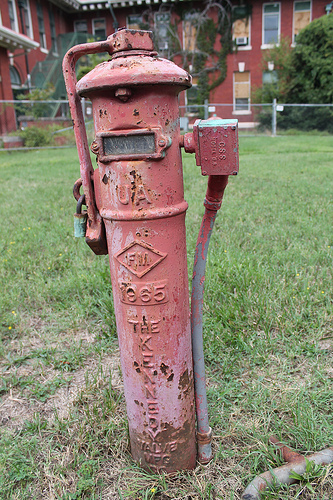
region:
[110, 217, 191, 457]
raised metal lettering of the fire hydrant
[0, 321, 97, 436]
sparse patches of brown dirt on the ground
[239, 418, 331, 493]
grey metal pipe on the ground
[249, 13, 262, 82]
red brick wall of the building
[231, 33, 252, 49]
an air conditioner in a window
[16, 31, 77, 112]
green cage over the stairwell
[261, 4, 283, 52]
white trim of the window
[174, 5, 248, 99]
green vines growing on the building wall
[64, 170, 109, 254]
rusted lock on the fire hydrant lever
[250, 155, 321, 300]
green grass of the courtyard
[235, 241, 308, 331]
green grass of the ground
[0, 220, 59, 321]
yellow flowers growing on the ground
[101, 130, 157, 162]
clear glass plate on the front of the fire hydrant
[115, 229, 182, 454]
raised metal lettering on the fire hydrant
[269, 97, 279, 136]
grey metal post of a fence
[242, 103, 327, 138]
grey metal chain link fence next to the field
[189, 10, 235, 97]
green vines growing on the side of the building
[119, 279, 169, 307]
1965 stamped on metal utility box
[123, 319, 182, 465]
Manufacturer identification stamped on utility box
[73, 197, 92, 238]
Padlock securing access to utility flow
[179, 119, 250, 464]
Electric power supply to utility box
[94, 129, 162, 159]
Occluded information window on box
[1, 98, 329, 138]
Chain link fence in background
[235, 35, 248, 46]
Air conditioning unit in building window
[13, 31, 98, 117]
Stairway leading to second floor of building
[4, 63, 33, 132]
Arched entry way to building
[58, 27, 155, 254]
Utility flow control handle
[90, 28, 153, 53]
top part of the machine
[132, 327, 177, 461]
name on the hydrant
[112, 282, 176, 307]
number on the hydrant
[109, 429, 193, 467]
paint gone in buttom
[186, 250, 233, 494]
a pipe near hydrant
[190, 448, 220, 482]
a pipe digged into ground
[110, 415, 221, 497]
a hydrant digged into ground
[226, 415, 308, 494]
a stick in the side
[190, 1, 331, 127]
a big home in the back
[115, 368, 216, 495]
the rust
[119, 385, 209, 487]
the rust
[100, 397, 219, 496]
the rust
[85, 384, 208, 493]
the rust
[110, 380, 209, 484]
the rust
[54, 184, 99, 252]
the lock is old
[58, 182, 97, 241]
the lock is old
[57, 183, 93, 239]
the lock is old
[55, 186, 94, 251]
the lock is old